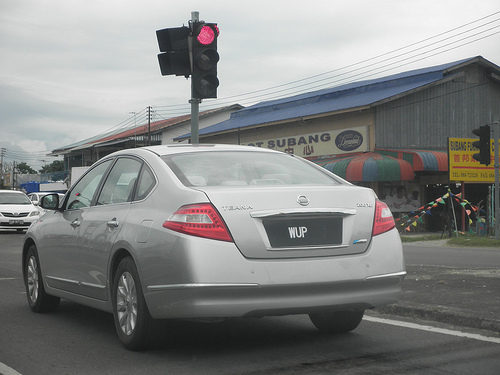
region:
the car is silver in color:
[23, 150, 418, 344]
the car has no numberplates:
[266, 206, 348, 246]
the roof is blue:
[225, 72, 401, 109]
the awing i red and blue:
[338, 150, 413, 187]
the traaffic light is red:
[186, 25, 227, 110]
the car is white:
[2, 183, 38, 236]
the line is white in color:
[392, 310, 479, 343]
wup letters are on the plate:
[281, 220, 319, 247]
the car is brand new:
[22, 163, 406, 349]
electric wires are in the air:
[327, 60, 443, 80]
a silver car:
[18, 149, 408, 342]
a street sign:
[178, 18, 220, 100]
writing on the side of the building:
[255, 136, 367, 153]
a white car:
[1, 190, 42, 225]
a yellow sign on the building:
[446, 131, 498, 183]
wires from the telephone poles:
[67, 48, 487, 107]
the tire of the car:
[108, 261, 153, 340]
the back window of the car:
[175, 150, 332, 185]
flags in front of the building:
[389, 181, 483, 236]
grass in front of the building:
[446, 230, 498, 242]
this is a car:
[51, 163, 376, 303]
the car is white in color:
[174, 248, 226, 287]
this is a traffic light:
[191, 18, 228, 110]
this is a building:
[343, 88, 430, 153]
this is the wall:
[410, 102, 439, 140]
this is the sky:
[46, 18, 130, 85]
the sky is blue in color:
[6, 94, 30, 136]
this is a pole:
[187, 95, 216, 147]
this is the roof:
[268, 101, 321, 116]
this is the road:
[429, 258, 491, 365]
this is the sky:
[33, 13, 80, 35]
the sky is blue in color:
[18, 10, 55, 35]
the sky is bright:
[63, 34, 125, 57]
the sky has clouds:
[45, 22, 85, 64]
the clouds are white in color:
[32, 20, 97, 74]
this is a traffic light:
[153, 22, 217, 102]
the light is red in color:
[203, 30, 211, 43]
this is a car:
[16, 149, 401, 341]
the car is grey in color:
[153, 253, 204, 273]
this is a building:
[384, 63, 471, 145]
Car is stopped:
[12, 138, 405, 343]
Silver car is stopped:
[16, 135, 406, 346]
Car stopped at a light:
[20, 135, 405, 340]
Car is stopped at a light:
[15, 136, 415, 346]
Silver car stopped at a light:
[15, 140, 411, 350]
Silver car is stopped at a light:
[16, 140, 408, 350]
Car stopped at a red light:
[12, 137, 417, 347]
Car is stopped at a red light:
[16, 137, 416, 349]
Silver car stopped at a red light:
[20, 142, 419, 348]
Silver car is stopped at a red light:
[18, 135, 415, 352]